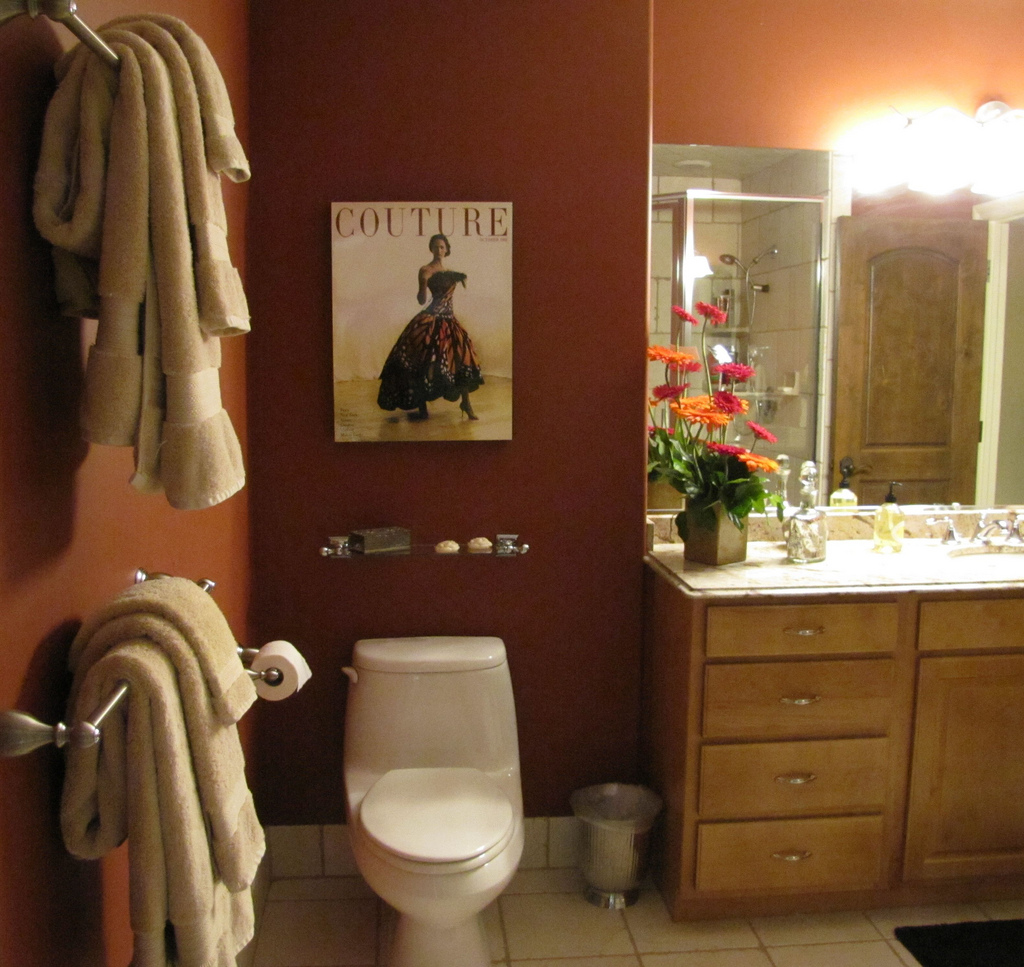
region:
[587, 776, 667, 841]
a bag in a garbage can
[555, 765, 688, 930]
a garbage can in the bathroom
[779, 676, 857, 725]
handle on a draw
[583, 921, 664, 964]
tiles on the floor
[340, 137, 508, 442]
a picture on the wall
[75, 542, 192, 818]
a towel on a rack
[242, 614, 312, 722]
toilet paper on the roll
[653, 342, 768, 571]
flowers on the counter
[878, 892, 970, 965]
a rug on the floor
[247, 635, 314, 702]
A toilet paper dispenser complete with roll.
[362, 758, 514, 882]
A white closed toilet seat.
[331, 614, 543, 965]
A white porcelain toilet.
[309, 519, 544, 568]
Miscellaneous toiletries on a clear shelf.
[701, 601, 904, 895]
Four wooden dresser drawers with silver handles.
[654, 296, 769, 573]
Red and orange flowers in a metal vase.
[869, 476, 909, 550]
A lotion dispenser with black nozzle.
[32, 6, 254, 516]
Cream colored towel on towel rack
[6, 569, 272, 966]
Cream colored towel on towel rack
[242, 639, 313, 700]
Toilet paper on roll holder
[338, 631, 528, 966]
White toilet against wall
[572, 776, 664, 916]
Small trash can next to vanity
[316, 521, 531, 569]
Glass shelf with knick knacks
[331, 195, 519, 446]
Art picture on wall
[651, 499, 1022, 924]
Wooden vanity with white top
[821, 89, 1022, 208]
Light fixture above mirror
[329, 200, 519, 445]
Picture above the toilet that says COUTURE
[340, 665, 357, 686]
White flusher on the toilet.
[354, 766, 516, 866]
A white toilet seat.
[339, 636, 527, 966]
A white toilet with seat down.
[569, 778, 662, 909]
A silver trashcan with plastic bag.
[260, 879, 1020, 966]
A white tiled floor.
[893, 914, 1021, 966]
A black rug on the floor.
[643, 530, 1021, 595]
A mostly white counter top.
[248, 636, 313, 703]
White roll of toilet paper.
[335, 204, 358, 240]
Red C in COUTURE.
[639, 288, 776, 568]
red and orange floral display on vanity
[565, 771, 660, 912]
silver waste paper basket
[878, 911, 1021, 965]
a black throw rug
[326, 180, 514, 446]
framed poster size magazine cover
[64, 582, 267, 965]
plush white towels on a towel bar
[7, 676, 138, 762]
brushed nickel towel bars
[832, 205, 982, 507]
natural wood arched paneled door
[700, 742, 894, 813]
drawer is light brown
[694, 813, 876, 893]
drawer is light brown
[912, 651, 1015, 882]
drawer is light brown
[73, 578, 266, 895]
towel is white and soft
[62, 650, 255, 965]
towel is white and soft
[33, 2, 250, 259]
towel is white and soft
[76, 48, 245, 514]
towel is white and soft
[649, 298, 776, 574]
Pink and orange flowers in container.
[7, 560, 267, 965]
Beige towel hanging on rack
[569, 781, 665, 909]
trashcan on floor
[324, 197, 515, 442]
picture of a lady in a dress above toilet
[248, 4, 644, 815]
burgandy painted wall behind toilet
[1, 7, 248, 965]
wall painted burnt orange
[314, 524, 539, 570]
soap rack on wall behind toilet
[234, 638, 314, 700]
used roll of toilet paper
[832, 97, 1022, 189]
bright lights above mirror